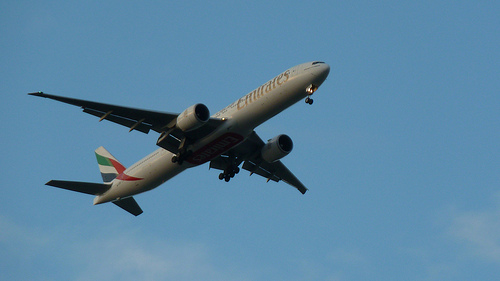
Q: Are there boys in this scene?
A: No, there are no boys.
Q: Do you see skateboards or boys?
A: No, there are no boys or skateboards.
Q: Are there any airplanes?
A: Yes, there is an airplane.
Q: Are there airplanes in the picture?
A: Yes, there is an airplane.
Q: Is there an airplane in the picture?
A: Yes, there is an airplane.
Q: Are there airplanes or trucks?
A: Yes, there is an airplane.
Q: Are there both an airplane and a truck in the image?
A: No, there is an airplane but no trucks.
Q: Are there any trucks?
A: No, there are no trucks.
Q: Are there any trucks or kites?
A: No, there are no trucks or kites.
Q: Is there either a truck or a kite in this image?
A: No, there are no trucks or kites.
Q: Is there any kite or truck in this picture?
A: No, there are no trucks or kites.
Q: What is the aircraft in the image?
A: The aircraft is an airplane.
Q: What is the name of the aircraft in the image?
A: The aircraft is an airplane.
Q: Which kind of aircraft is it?
A: The aircraft is an airplane.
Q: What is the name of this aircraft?
A: This is an airplane.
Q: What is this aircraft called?
A: This is an airplane.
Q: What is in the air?
A: The plane is in the air.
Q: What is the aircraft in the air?
A: The aircraft is an airplane.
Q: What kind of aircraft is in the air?
A: The aircraft is an airplane.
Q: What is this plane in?
A: The plane is in the air.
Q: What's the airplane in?
A: The plane is in the air.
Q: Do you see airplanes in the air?
A: Yes, there is an airplane in the air.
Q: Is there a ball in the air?
A: No, there is an airplane in the air.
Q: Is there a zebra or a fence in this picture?
A: No, there are no fences or zebras.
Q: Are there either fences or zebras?
A: No, there are no fences or zebras.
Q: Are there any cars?
A: No, there are no cars.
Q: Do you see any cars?
A: No, there are no cars.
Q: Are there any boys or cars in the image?
A: No, there are no cars or boys.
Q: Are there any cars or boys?
A: No, there are no cars or boys.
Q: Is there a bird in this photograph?
A: No, there are no birds.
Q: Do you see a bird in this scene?
A: No, there are no birds.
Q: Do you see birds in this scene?
A: No, there are no birds.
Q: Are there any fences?
A: No, there are no fences.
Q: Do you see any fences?
A: No, there are no fences.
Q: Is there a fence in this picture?
A: No, there are no fences.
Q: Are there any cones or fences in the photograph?
A: No, there are no fences or cones.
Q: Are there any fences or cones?
A: No, there are no fences or cones.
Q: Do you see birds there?
A: No, there are no birds.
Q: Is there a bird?
A: No, there are no birds.